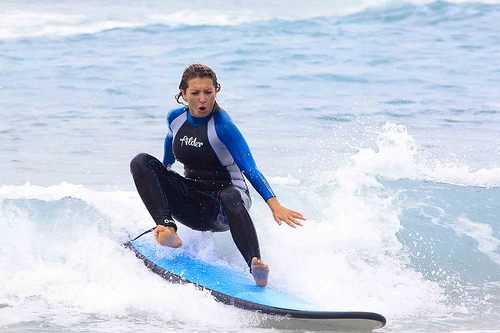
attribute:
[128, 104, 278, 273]
wetsuit — wearing, black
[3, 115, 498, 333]
wave — white, blue, ocean, beach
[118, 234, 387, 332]
surfboard — blue, surf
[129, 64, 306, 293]
surfer — female, falling back, surfing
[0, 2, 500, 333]
ocean — clear, white, blue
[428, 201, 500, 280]
foam — white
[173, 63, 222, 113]
hair — brown